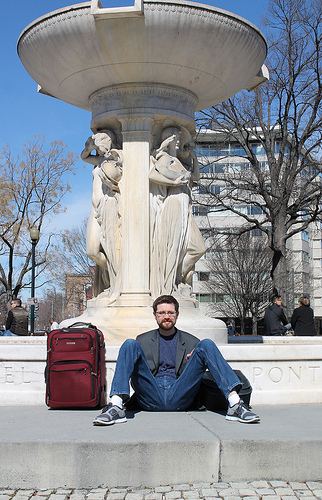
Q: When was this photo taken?
A: During the day.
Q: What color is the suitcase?
A: Red.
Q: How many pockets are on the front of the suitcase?
A: Two.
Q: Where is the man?
A: In front of a statue.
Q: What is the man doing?
A: Sitting down.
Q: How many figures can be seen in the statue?
A: Two.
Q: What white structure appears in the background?
A: A building.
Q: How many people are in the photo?
A: Six.